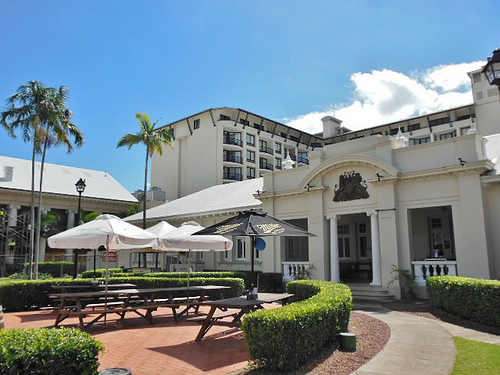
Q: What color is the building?
A: White.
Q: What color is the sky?
A: Blue.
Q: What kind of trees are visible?
A: Palm trees.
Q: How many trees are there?
A: 3.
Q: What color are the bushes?
A: Green.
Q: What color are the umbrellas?
A: White and black.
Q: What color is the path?
A: Gray.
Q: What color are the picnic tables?
A: Brown.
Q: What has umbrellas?
A: Picnic tables.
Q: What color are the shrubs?
A: Green.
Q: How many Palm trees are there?
A: Three.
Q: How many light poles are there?
A: One.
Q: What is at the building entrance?
A: Two white columns.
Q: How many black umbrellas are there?
A: One.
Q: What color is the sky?
A: Blue.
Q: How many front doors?
A: One.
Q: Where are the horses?
A: No horses.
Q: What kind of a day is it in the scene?
A: Sunny.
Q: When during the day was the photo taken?
A: Daytime.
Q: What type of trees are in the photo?
A: Palm.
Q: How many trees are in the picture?
A: Three.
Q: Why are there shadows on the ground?
A: The sun is out.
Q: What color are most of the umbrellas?
A: White.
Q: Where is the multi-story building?
A: Behind the other building.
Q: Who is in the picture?
A: No one.